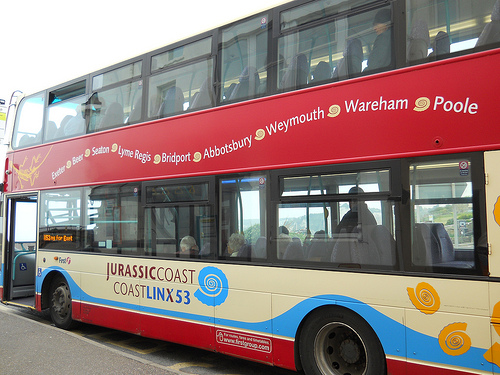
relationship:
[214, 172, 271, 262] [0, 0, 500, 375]
window of a bus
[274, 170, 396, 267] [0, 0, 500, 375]
window of a bus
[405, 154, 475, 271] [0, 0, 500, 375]
window of a bus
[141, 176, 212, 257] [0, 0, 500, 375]
window of a bus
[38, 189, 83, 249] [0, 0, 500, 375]
window of a bus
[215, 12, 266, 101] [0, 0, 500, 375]
window on bus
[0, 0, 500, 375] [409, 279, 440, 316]
bus has swirls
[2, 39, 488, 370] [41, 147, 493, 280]
bus has window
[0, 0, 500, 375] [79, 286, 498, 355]
bus has bottom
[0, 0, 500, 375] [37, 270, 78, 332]
bus has bus wheel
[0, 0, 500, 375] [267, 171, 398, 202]
bus has window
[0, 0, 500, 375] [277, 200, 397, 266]
bus has window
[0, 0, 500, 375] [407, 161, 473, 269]
bus has window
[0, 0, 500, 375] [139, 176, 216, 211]
bus has window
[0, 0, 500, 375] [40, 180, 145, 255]
bus has window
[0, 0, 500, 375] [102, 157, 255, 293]
bus has window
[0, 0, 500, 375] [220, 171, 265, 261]
bus has window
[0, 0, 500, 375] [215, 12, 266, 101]
bus has window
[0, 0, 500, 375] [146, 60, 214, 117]
bus has window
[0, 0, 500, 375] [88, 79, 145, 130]
bus has window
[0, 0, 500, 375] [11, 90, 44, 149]
bus has window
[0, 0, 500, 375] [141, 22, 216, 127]
bus has window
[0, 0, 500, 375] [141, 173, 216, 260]
bus has window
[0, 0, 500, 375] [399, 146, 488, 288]
bus has window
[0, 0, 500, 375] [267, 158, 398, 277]
bus has window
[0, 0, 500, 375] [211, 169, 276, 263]
bus has window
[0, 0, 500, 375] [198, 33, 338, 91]
bus has window